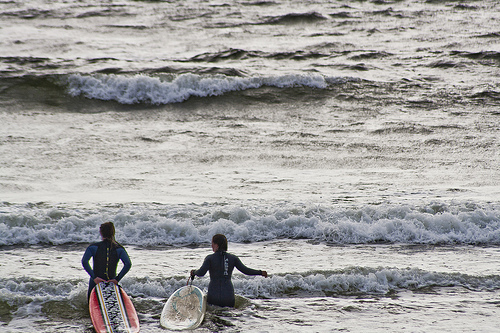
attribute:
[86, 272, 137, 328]
surfboard — red, white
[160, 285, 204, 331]
surfboard — blue, white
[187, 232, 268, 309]
girl — second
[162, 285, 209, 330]
surfboard — white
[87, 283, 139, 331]
surfboard — red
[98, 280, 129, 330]
stripe — white, blue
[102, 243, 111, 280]
detailing — yellow